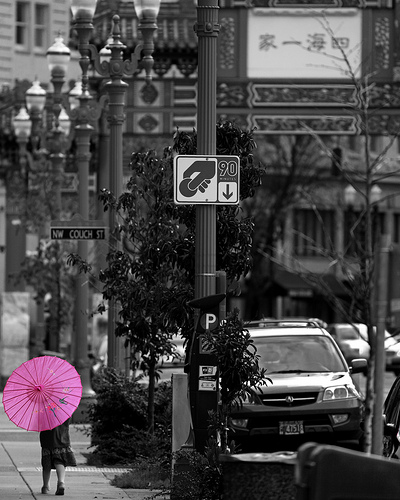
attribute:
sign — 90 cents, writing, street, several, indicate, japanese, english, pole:
[162, 145, 256, 207]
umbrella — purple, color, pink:
[2, 348, 90, 431]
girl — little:
[24, 404, 78, 498]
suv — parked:
[196, 289, 363, 479]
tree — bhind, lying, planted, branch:
[104, 165, 265, 410]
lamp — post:
[78, 13, 165, 114]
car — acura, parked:
[210, 326, 346, 460]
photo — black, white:
[12, 31, 385, 469]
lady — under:
[2, 279, 122, 477]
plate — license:
[256, 414, 317, 457]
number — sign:
[220, 159, 239, 181]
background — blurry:
[67, 54, 344, 299]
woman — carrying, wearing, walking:
[0, 331, 98, 491]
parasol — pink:
[27, 377, 68, 413]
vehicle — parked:
[276, 300, 375, 409]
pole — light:
[61, 100, 153, 256]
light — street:
[23, 28, 96, 133]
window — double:
[17, 9, 67, 50]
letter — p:
[174, 144, 241, 185]